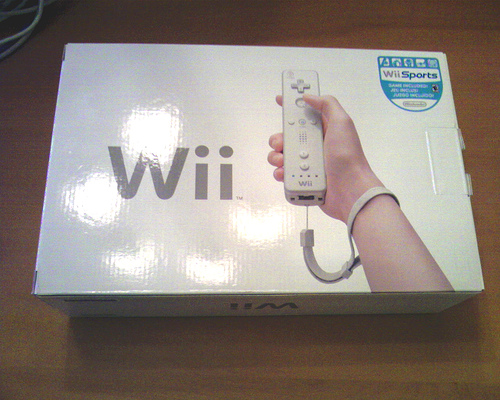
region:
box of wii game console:
[29, 40, 483, 320]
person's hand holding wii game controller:
[264, 69, 453, 294]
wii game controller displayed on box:
[277, 65, 328, 208]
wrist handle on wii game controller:
[300, 187, 400, 282]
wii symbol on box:
[104, 141, 246, 204]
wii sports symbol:
[372, 52, 442, 113]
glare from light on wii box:
[117, 98, 182, 162]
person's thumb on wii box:
[302, 90, 346, 127]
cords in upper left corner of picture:
[0, 2, 47, 59]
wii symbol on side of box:
[225, 302, 297, 317]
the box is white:
[21, 27, 488, 329]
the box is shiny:
[55, 52, 461, 296]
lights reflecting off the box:
[70, 80, 300, 280]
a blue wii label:
[357, 42, 445, 126]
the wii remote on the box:
[237, 57, 403, 262]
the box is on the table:
[15, 36, 469, 363]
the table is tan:
[0, 292, 364, 387]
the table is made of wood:
[22, 308, 438, 390]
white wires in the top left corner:
[1, 4, 63, 36]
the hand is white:
[261, 65, 470, 312]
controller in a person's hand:
[232, 54, 401, 229]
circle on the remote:
[285, 158, 321, 184]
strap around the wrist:
[331, 176, 421, 261]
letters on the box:
[109, 132, 251, 221]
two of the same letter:
[181, 131, 249, 208]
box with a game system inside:
[3, 28, 458, 286]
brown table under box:
[226, 335, 311, 397]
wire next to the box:
[0, 7, 55, 47]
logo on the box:
[361, 25, 460, 133]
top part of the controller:
[277, 58, 327, 90]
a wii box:
[40, 20, 494, 360]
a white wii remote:
[244, 42, 411, 247]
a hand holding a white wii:
[197, 64, 439, 300]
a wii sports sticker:
[319, 23, 486, 162]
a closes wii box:
[10, 3, 499, 373]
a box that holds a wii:
[12, 10, 408, 392]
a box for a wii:
[33, 13, 496, 345]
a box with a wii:
[50, 22, 499, 345]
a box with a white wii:
[33, 20, 456, 397]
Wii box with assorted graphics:
[42, 38, 491, 280]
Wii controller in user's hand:
[253, 63, 358, 242]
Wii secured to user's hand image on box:
[246, 129, 439, 272]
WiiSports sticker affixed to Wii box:
[363, 49, 459, 114]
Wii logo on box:
[91, 132, 256, 228]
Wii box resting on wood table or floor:
[38, 38, 495, 350]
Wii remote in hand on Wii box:
[241, 56, 416, 291]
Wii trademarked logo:
[80, 126, 263, 238]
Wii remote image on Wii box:
[253, 61, 403, 281]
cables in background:
[3, 12, 90, 70]